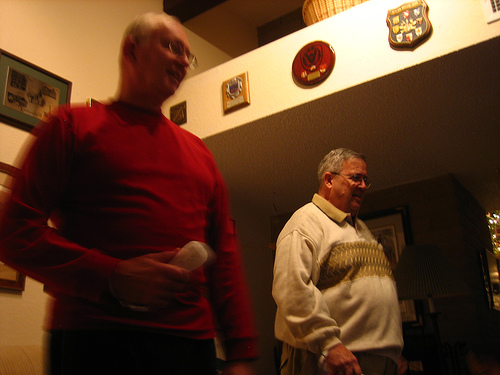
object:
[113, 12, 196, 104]
head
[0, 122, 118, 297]
arm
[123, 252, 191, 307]
hand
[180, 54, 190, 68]
nose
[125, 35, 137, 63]
ear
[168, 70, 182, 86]
mouth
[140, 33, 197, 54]
glasses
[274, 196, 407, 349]
sweater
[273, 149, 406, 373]
guy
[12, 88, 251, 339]
shirt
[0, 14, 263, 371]
man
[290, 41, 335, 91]
monument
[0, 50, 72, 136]
frame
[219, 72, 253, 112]
wall peice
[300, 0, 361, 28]
basket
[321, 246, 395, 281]
stripe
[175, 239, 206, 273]
remote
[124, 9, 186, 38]
hair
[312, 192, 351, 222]
collar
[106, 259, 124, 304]
clasp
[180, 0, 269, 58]
nook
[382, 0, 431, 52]
plaque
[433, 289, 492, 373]
dark